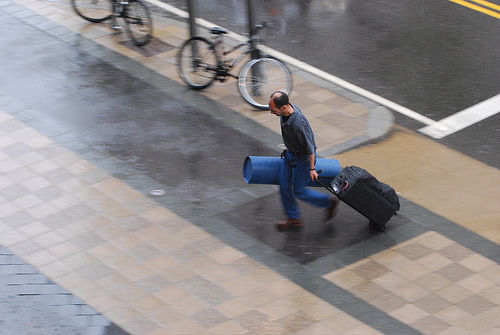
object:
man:
[266, 89, 341, 232]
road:
[151, 4, 497, 139]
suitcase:
[326, 164, 402, 234]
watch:
[310, 168, 315, 170]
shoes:
[275, 217, 305, 230]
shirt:
[279, 104, 318, 159]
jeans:
[275, 152, 338, 220]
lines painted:
[145, 0, 498, 144]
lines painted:
[434, 0, 498, 21]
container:
[242, 155, 341, 187]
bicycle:
[174, 20, 296, 110]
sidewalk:
[0, 0, 498, 331]